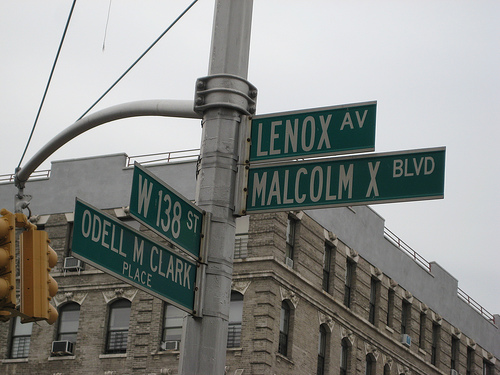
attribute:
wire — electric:
[78, 0, 198, 121]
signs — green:
[31, 100, 456, 318]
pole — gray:
[170, 11, 252, 371]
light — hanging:
[11, 206, 96, 323]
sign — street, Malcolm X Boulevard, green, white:
[241, 147, 444, 215]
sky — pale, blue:
[0, 1, 498, 311]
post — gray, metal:
[189, 7, 270, 369]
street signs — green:
[66, 99, 446, 316]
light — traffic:
[1, 216, 53, 318]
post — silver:
[199, 1, 301, 373]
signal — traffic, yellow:
[2, 207, 63, 326]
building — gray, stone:
[1, 148, 499, 372]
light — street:
[4, 197, 67, 329]